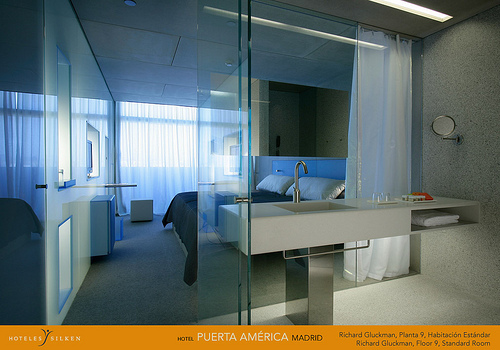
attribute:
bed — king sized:
[170, 157, 363, 235]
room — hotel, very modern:
[7, 13, 485, 326]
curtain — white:
[335, 25, 420, 278]